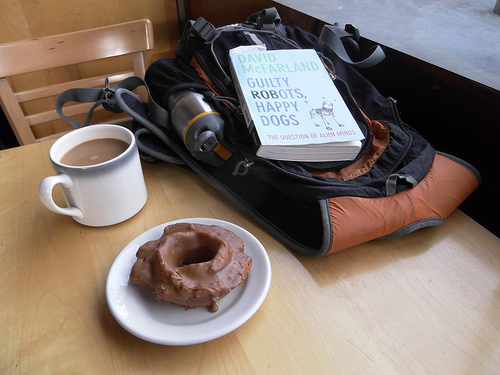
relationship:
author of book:
[240, 47, 323, 80] [225, 38, 361, 153]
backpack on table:
[50, 33, 496, 356] [6, 157, 489, 354]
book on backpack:
[225, 38, 361, 153] [53, 6, 483, 258]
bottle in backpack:
[140, 67, 237, 156] [53, 6, 483, 258]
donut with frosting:
[102, 219, 269, 315] [157, 218, 212, 249]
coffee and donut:
[21, 126, 173, 172] [102, 219, 269, 315]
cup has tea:
[20, 132, 191, 223] [70, 141, 113, 172]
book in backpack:
[225, 38, 361, 153] [53, 6, 483, 258]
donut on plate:
[102, 219, 269, 315] [77, 201, 289, 340]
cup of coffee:
[38, 124, 147, 227] [21, 126, 173, 172]